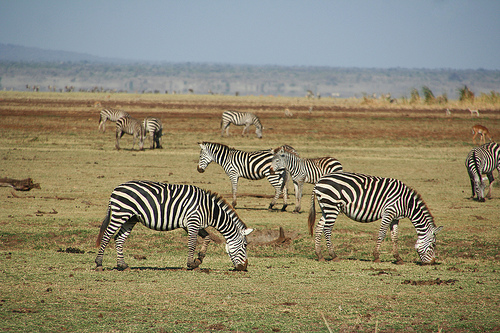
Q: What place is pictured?
A: It is a field.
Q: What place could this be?
A: It is a field.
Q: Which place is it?
A: It is a field.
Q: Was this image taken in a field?
A: Yes, it was taken in a field.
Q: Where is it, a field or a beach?
A: It is a field.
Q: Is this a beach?
A: No, it is a field.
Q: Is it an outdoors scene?
A: Yes, it is outdoors.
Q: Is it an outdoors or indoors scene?
A: It is outdoors.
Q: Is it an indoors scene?
A: No, it is outdoors.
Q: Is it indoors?
A: No, it is outdoors.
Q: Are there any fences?
A: No, there are no fences.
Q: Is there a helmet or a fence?
A: No, there are no fences or helmets.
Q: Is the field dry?
A: Yes, the field is dry.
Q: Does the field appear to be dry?
A: Yes, the field is dry.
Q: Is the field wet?
A: No, the field is dry.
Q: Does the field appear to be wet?
A: No, the field is dry.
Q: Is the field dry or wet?
A: The field is dry.